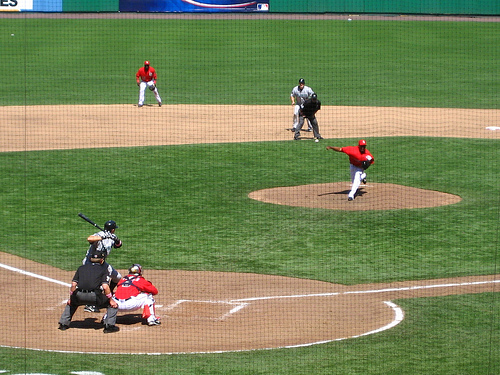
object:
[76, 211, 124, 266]
batter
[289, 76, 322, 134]
runner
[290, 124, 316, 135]
plate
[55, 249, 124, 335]
umpire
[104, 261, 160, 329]
catcher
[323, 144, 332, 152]
hand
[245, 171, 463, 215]
mound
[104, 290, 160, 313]
plate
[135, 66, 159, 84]
catcher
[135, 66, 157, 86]
red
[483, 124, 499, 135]
base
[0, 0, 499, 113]
outfield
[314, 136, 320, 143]
baseball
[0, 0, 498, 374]
air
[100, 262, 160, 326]
position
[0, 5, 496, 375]
field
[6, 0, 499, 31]
fence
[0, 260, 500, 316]
line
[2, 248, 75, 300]
part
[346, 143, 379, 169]
top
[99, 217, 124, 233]
helmet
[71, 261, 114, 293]
top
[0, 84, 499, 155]
part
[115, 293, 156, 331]
trouser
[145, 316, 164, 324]
shoe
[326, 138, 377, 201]
man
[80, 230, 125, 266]
uniform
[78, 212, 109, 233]
bat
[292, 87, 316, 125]
uniform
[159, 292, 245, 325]
marking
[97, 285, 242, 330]
base